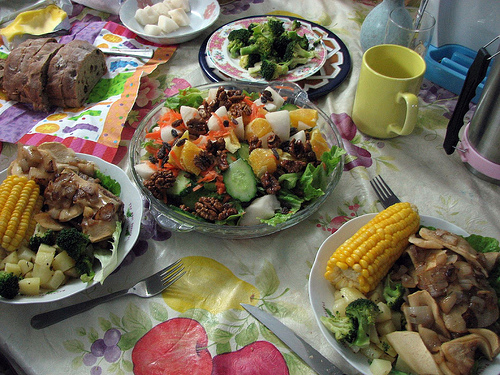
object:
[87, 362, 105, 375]
grapes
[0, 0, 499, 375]
cloth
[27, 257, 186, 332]
fork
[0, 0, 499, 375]
table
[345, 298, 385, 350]
brocolli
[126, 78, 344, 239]
plate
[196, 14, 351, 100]
plate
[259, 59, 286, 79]
brocolli